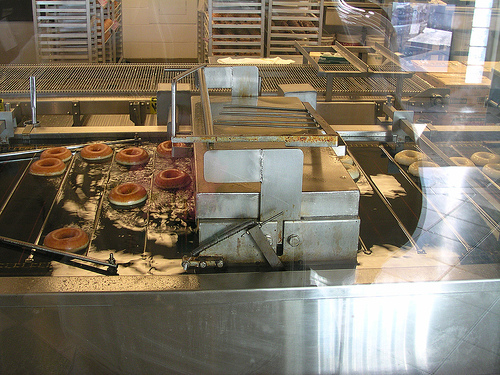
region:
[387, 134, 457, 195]
uncooked donuts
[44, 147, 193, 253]
donuts on conveyor belt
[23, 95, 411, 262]
donuts being made in bakery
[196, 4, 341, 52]
racks of pastries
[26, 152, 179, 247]
donuts in hot oil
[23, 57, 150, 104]
top of conveyor belt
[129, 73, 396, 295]
silver colored cooking machinery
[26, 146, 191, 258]
8 donuts being baked in oil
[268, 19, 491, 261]
bakery showing donut production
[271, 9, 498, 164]
reflection of someone in bakery window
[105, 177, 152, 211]
A donut in oil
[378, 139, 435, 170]
Doughnuts being made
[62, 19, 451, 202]
A ktchen in a bakery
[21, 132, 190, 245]
Fresh made doughnuts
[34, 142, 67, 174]
Doughnuts not frosted yet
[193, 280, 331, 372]
Stainless steel equipment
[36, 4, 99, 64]
Racks for holding trays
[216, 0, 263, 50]
Doughnuts on trays in racks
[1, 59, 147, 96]
A coneyor belt in a bakery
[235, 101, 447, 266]
A doughnut making machine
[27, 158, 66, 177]
a plain glazed doughnut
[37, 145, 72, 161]
a plain glazed doughnut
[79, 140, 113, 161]
a plain glazed doughnut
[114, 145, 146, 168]
a plain glazed doughnut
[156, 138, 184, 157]
a plain glazed doughnut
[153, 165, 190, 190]
a plain glazed doughnut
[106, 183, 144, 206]
a plain glazed doughnut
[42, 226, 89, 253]
a plain glazed doughnut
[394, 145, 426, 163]
a plain unglazed doughnut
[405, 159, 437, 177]
a plain unglazed doughnut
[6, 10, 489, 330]
krispy kreme doughnut factory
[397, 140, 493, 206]
doughnuts ready to be fried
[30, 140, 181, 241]
freshly fried doughnuts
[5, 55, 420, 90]
moving line for doughnuts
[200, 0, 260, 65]
bakers rack full of doughnuts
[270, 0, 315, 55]
bakers rack full of doughnuts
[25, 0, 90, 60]
empty backers rack empty of doughnuts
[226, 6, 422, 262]
reflection of person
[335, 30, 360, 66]
5 gallon bucket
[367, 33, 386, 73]
5 gallon bucket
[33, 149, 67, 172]
Two donuts next to each other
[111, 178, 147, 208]
Half of the donut is fried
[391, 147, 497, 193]
The donuts haven't been cooked yet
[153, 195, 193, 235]
The liquid has ripples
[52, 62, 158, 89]
An empty conveyor belt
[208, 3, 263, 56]
Racks for the donuts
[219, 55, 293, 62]
White towel on a table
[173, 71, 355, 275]
A portion of a metal machine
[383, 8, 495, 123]
The window has a glare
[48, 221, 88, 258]
A single donut in liquid